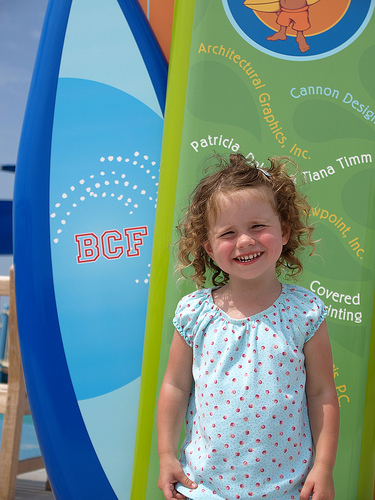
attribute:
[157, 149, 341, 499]
girl — little, smiling, grinning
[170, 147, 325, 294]
hair — curly, red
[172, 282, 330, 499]
shirt — mostly blue, pale blue, blue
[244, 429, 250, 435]
dot — pink, red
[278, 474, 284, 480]
dot — pink, red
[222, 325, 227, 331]
dot — pink, red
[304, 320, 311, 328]
dot — pink, red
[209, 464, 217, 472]
dot — pink, red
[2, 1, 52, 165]
sky — blue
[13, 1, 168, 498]
surfboard — blue, dotted, trimmed in blue, light blue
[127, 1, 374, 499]
surfboard — green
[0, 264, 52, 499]
stand — wooden, brown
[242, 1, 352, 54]
character — cartoon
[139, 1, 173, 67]
surfboard — orange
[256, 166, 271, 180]
ribbon — blue, white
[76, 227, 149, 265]
word — red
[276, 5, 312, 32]
shorts — orange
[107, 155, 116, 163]
spot — white, small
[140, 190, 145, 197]
spot — white, small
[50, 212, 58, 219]
spot — small, white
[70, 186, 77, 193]
spot — white, small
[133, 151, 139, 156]
spot — white, small